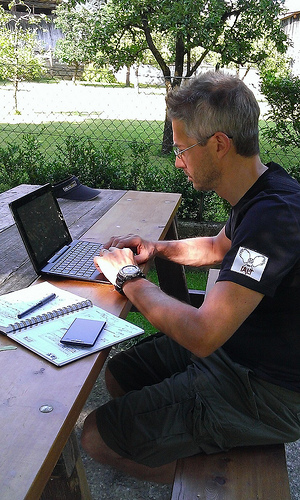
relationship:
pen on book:
[17, 292, 55, 319] [0, 279, 144, 368]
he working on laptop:
[80, 70, 300, 487] [19, 176, 137, 291]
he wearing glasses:
[90, 70, 282, 492] [173, 130, 232, 159]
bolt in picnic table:
[28, 399, 58, 417] [0, 181, 292, 500]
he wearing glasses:
[80, 70, 300, 487] [173, 130, 232, 159]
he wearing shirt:
[80, 70, 300, 487] [204, 212, 286, 397]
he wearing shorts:
[80, 70, 300, 487] [105, 346, 269, 442]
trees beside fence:
[7, 4, 295, 76] [6, 54, 171, 179]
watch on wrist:
[105, 250, 148, 298] [95, 255, 146, 292]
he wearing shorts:
[80, 70, 300, 487] [117, 347, 271, 435]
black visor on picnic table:
[49, 174, 102, 201] [0, 182, 290, 498]